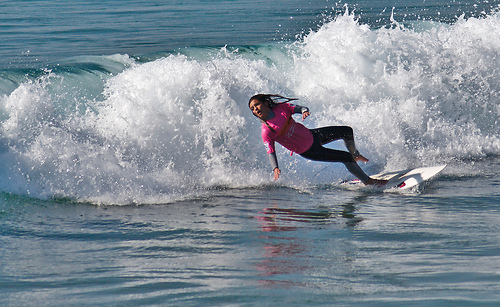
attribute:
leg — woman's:
[309, 112, 370, 161]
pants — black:
[307, 121, 372, 166]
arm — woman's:
[249, 140, 314, 210]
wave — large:
[8, 4, 498, 188]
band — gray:
[267, 158, 283, 166]